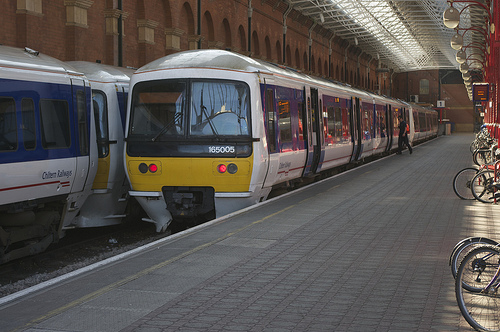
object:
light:
[149, 163, 157, 172]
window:
[266, 86, 296, 148]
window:
[125, 83, 177, 139]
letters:
[41, 169, 75, 178]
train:
[0, 52, 99, 233]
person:
[393, 116, 415, 153]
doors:
[383, 104, 394, 155]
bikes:
[467, 164, 497, 203]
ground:
[156, 189, 469, 321]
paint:
[69, 282, 144, 298]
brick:
[46, 7, 69, 55]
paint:
[31, 85, 74, 100]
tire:
[450, 165, 487, 200]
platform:
[360, 132, 497, 332]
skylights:
[440, 10, 479, 27]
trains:
[115, 45, 452, 197]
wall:
[0, 0, 442, 115]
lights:
[216, 164, 227, 172]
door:
[301, 87, 324, 175]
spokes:
[468, 180, 482, 197]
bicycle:
[452, 240, 497, 332]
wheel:
[449, 253, 497, 320]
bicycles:
[447, 232, 499, 293]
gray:
[225, 246, 404, 329]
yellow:
[159, 159, 223, 187]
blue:
[18, 84, 84, 104]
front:
[128, 68, 252, 192]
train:
[123, 52, 442, 196]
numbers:
[209, 144, 237, 153]